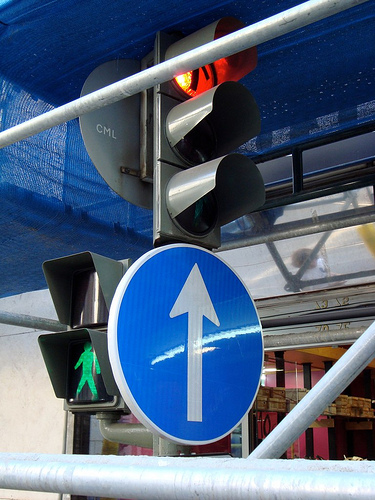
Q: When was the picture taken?
A: During the day.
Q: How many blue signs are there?
A: One.